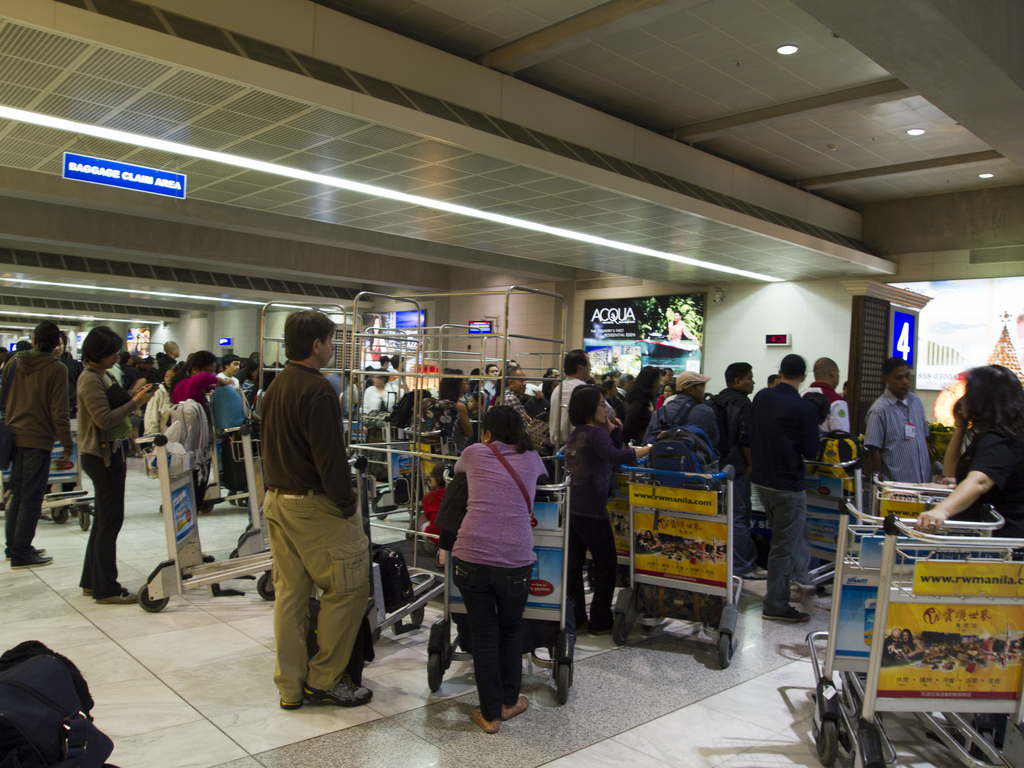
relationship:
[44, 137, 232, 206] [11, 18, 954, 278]
sign hanging from ceiling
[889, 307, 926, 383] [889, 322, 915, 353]
sign has a number 4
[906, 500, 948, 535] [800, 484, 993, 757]
hand placed on luggage cart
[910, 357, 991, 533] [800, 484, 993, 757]
person leaning on luggage cart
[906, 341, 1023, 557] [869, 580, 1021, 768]
person standing next to luggage carts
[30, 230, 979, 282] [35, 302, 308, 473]
baggage claim area written on overhead sign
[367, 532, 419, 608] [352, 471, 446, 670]
luggage on cart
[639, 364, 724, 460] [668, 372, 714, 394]
man wearing hat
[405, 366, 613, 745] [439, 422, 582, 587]
woman wears top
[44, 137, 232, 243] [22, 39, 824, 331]
sign on ceiling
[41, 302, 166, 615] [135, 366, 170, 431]
people looking at phone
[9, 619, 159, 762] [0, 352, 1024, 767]
bag on floor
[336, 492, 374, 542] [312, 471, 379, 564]
hand on pocket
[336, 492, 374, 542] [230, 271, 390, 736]
hand on man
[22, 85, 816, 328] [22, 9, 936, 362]
light on ceiling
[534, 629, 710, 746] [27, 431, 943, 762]
tile on floor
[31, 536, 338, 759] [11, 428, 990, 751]
tile on floor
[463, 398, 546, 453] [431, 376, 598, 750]
hair on woman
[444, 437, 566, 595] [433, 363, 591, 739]
shirt on woman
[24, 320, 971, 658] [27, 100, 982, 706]
people in airport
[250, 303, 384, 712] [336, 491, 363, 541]
man has h hand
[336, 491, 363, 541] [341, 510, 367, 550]
hand in h pocket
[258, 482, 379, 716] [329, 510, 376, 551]
pants have pocket